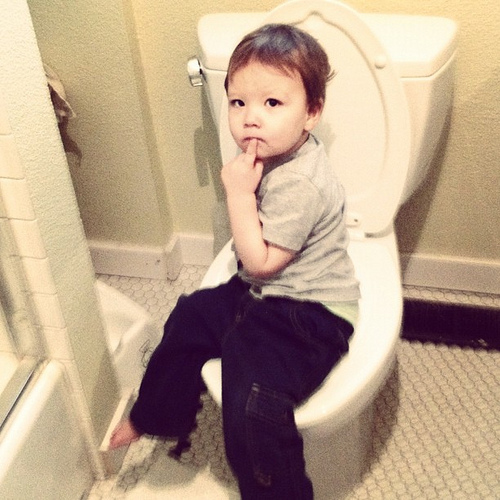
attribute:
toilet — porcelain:
[341, 2, 450, 476]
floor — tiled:
[384, 356, 500, 498]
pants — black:
[122, 278, 359, 500]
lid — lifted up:
[317, 4, 419, 238]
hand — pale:
[216, 137, 267, 198]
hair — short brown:
[206, 16, 338, 119]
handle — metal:
[181, 52, 210, 95]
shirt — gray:
[221, 139, 367, 324]